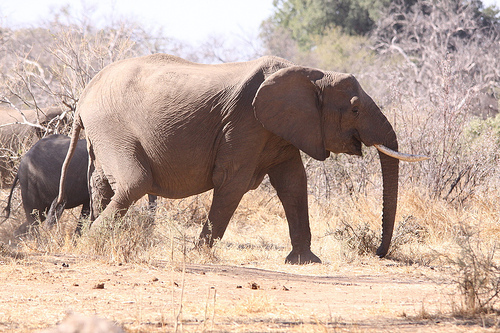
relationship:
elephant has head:
[40, 26, 431, 267] [265, 57, 407, 175]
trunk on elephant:
[362, 141, 412, 286] [40, 26, 431, 267]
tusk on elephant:
[358, 135, 421, 164] [40, 26, 431, 267]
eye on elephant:
[347, 93, 367, 120] [40, 26, 431, 267]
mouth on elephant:
[340, 127, 373, 155] [40, 26, 431, 267]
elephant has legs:
[40, 26, 431, 267] [80, 145, 338, 269]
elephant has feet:
[40, 26, 431, 267] [65, 209, 333, 266]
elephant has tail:
[40, 26, 431, 267] [41, 117, 95, 219]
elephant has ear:
[40, 26, 431, 267] [232, 60, 341, 165]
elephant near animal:
[40, 26, 431, 267] [10, 135, 166, 247]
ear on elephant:
[232, 60, 341, 165] [40, 26, 431, 267]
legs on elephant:
[80, 145, 338, 269] [40, 26, 431, 267]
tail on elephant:
[41, 117, 95, 219] [40, 26, 431, 267]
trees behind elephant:
[1, 2, 499, 195] [40, 26, 431, 267]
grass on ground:
[22, 202, 465, 267] [1, 206, 499, 332]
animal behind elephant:
[10, 135, 166, 247] [40, 26, 431, 267]